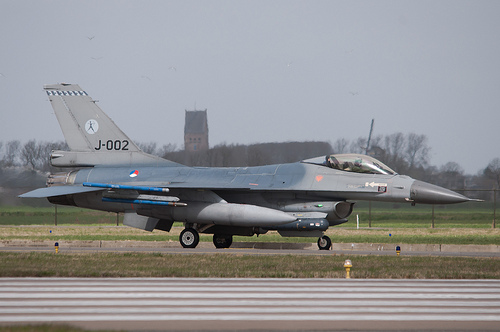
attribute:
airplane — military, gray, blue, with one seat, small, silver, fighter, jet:
[19, 83, 484, 251]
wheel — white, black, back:
[182, 231, 195, 244]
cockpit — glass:
[300, 154, 402, 176]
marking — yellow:
[343, 259, 353, 279]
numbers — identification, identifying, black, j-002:
[94, 138, 130, 152]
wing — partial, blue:
[117, 181, 252, 191]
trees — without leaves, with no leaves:
[0, 141, 71, 172]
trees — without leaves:
[335, 134, 431, 168]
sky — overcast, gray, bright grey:
[1, 1, 500, 175]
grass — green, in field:
[0, 206, 499, 244]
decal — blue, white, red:
[128, 167, 139, 178]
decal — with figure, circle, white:
[84, 118, 100, 134]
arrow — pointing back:
[368, 180, 390, 187]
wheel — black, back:
[214, 232, 229, 247]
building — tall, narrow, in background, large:
[165, 110, 333, 168]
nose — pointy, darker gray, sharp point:
[413, 181, 485, 205]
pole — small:
[356, 213, 361, 229]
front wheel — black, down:
[316, 235, 331, 250]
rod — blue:
[82, 181, 170, 192]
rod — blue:
[103, 196, 188, 207]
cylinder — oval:
[136, 202, 297, 222]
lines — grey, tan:
[1, 276, 500, 324]